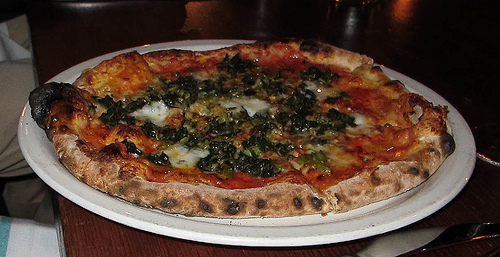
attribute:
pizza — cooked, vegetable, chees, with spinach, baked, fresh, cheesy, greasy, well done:
[25, 38, 460, 223]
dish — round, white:
[14, 34, 482, 253]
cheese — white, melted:
[217, 91, 270, 119]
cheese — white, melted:
[128, 96, 172, 128]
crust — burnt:
[24, 74, 93, 144]